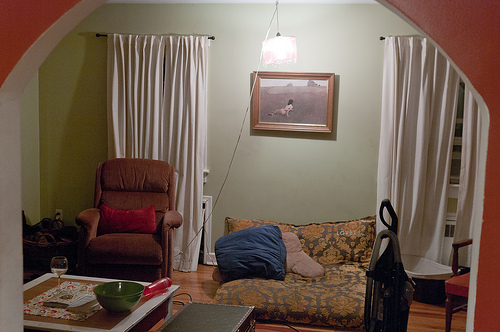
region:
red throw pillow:
[96, 194, 166, 239]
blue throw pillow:
[209, 229, 292, 283]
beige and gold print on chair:
[223, 199, 387, 329]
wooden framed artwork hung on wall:
[241, 60, 353, 155]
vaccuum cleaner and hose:
[361, 178, 429, 329]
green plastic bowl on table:
[88, 273, 160, 319]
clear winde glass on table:
[43, 248, 80, 305]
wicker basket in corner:
[21, 205, 99, 282]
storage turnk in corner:
[163, 293, 269, 330]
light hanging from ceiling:
[256, 7, 311, 78]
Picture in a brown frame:
[248, 64, 341, 148]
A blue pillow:
[212, 228, 299, 287]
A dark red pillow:
[95, 198, 164, 242]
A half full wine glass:
[49, 253, 80, 304]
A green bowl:
[87, 275, 144, 321]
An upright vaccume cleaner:
[361, 194, 419, 330]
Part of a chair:
[436, 227, 473, 330]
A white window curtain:
[363, 25, 459, 276]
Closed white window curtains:
[104, 26, 244, 278]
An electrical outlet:
[54, 206, 66, 223]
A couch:
[225, 158, 323, 328]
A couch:
[274, 221, 322, 327]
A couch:
[253, 186, 348, 328]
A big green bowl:
[92, 276, 149, 319]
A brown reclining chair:
[83, 155, 184, 290]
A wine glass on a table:
[37, 250, 94, 317]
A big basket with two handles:
[22, 217, 78, 275]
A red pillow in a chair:
[91, 201, 172, 246]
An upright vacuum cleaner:
[367, 202, 426, 329]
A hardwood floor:
[177, 264, 214, 301]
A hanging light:
[250, 5, 319, 76]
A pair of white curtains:
[92, 27, 216, 269]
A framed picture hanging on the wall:
[241, 64, 356, 149]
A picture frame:
[213, 14, 422, 246]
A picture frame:
[245, 61, 359, 196]